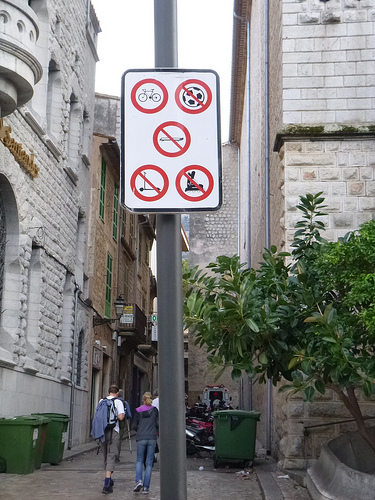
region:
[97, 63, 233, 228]
Sign on a pole.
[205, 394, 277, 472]
Dumpster in an alley.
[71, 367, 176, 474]
People walking down an alley.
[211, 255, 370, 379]
The leaves are green.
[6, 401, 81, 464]
Two dumpsters side by side.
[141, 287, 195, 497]
The pole is grey.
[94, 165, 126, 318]
The shutters are green.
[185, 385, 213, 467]
Bikes parked in an alley.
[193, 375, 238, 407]
A car parked in an alley.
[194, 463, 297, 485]
Litter on the ground.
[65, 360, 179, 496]
People walking into an alley.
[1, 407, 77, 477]
Three green garbage cans on the left.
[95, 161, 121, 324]
Three windows with green frames.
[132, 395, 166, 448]
Black hoodie with a purple liner.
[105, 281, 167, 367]
Balconies on the left.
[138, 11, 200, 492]
Grey sign post.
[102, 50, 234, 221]
One sign with five instructions.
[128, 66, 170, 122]
Bicycling is allowed.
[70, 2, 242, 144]
Hazy grey sky.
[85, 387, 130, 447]
Backpack on the man's back.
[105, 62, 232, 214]
a red white and black street sign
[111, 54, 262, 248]
a street sign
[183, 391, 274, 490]
a green dumpster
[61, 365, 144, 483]
a person wearing a back pack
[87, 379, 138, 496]
a person wearing a white shirt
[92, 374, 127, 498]
a person wearing capris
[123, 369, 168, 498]
a person wearing a black and purple sweatshirt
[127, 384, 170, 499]
a person with a pony tail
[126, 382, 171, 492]
a person wearing blue jeans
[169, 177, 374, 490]
a tall green tree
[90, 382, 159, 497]
The people walking down the alley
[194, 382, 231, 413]
The truck in the alley way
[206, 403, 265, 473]
The single green trash can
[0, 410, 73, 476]
The three trash cans lined up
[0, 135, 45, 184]
The gold writing on the building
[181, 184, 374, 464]
The tree in the planter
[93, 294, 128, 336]
The light hanging of the building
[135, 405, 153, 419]
The pink and grey hood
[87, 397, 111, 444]
The blue towel on the back pack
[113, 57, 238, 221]
The red white and black sign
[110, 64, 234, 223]
sign is red and white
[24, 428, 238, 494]
street is grey and concrete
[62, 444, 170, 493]
street is grey and concrete